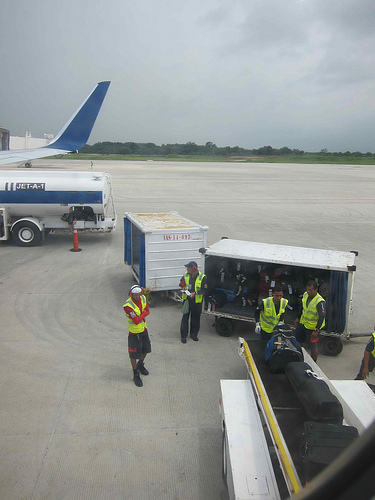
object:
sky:
[1, 0, 371, 149]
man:
[124, 297, 150, 335]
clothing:
[123, 298, 149, 334]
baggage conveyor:
[239, 339, 373, 496]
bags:
[265, 336, 358, 461]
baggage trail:
[118, 207, 360, 347]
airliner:
[3, 79, 116, 164]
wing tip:
[34, 81, 117, 144]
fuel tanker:
[2, 167, 117, 243]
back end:
[31, 173, 119, 239]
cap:
[132, 284, 141, 294]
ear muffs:
[128, 289, 146, 292]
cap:
[127, 286, 147, 295]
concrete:
[12, 243, 135, 499]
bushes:
[95, 141, 373, 164]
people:
[116, 250, 331, 353]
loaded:
[243, 321, 304, 342]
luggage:
[282, 358, 344, 417]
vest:
[255, 298, 292, 329]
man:
[256, 284, 295, 339]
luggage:
[223, 262, 316, 308]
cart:
[198, 230, 366, 343]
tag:
[300, 362, 325, 380]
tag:
[304, 369, 325, 384]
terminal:
[10, 152, 371, 498]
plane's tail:
[61, 75, 114, 157]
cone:
[69, 218, 85, 258]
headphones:
[187, 260, 199, 276]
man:
[181, 261, 205, 344]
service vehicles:
[6, 166, 364, 341]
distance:
[57, 136, 373, 164]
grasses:
[97, 151, 370, 164]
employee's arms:
[124, 302, 151, 326]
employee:
[120, 283, 159, 387]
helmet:
[127, 284, 142, 301]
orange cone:
[61, 216, 89, 255]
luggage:
[206, 247, 344, 328]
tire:
[208, 314, 233, 333]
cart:
[193, 257, 345, 337]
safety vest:
[116, 299, 152, 329]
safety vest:
[175, 273, 209, 304]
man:
[176, 253, 213, 342]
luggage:
[306, 423, 363, 459]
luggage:
[269, 323, 310, 364]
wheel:
[8, 213, 45, 247]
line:
[102, 143, 365, 156]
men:
[107, 265, 330, 328]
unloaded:
[254, 308, 321, 351]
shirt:
[124, 299, 169, 327]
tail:
[42, 72, 127, 160]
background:
[89, 93, 371, 163]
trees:
[91, 134, 328, 159]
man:
[130, 278, 152, 385]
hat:
[125, 282, 147, 296]